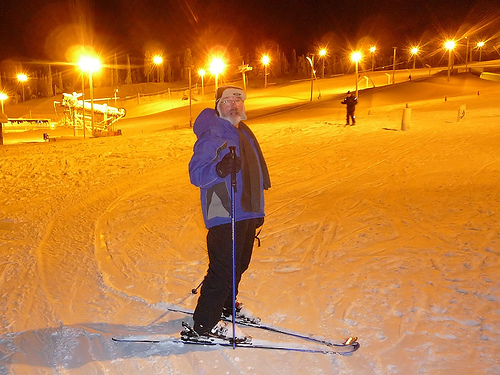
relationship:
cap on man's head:
[209, 83, 252, 103] [206, 79, 260, 129]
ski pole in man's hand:
[228, 146, 243, 350] [188, 141, 247, 185]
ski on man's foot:
[115, 294, 373, 363] [182, 213, 274, 345]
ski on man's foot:
[115, 294, 373, 363] [188, 213, 273, 330]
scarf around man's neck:
[226, 117, 278, 218] [216, 114, 256, 133]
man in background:
[339, 84, 371, 128] [22, 81, 484, 198]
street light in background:
[52, 35, 117, 134] [19, 85, 479, 185]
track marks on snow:
[31, 202, 122, 258] [15, 200, 173, 350]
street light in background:
[332, 35, 367, 103] [48, 63, 479, 153]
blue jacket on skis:
[178, 110, 275, 237] [109, 287, 381, 357]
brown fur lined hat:
[215, 84, 247, 122] [202, 82, 251, 113]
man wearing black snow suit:
[338, 88, 360, 128] [344, 98, 356, 117]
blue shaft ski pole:
[229, 197, 236, 212] [202, 136, 255, 352]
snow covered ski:
[6, 84, 499, 315] [110, 334, 362, 363]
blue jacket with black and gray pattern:
[186, 107, 271, 232] [199, 177, 231, 215]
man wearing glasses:
[187, 84, 266, 344] [210, 93, 250, 106]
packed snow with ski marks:
[29, 166, 182, 326] [28, 210, 115, 280]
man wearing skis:
[173, 69, 269, 352] [129, 291, 369, 359]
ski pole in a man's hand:
[216, 128, 258, 358] [180, 131, 248, 198]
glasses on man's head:
[213, 93, 247, 112] [199, 69, 256, 126]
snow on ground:
[47, 166, 457, 337] [6, 137, 496, 359]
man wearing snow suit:
[338, 88, 360, 128] [340, 95, 358, 126]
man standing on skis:
[187, 84, 266, 344] [107, 298, 362, 356]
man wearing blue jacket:
[187, 84, 266, 344] [186, 107, 271, 232]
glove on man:
[219, 152, 242, 178] [187, 84, 266, 344]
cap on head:
[214, 83, 250, 123] [220, 89, 247, 121]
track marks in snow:
[31, 189, 149, 336] [361, 232, 411, 302]